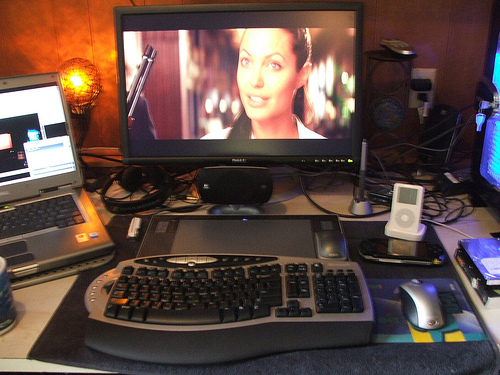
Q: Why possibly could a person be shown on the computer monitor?
A: Movie.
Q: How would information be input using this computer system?
A: Keyboard.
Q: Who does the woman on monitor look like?
A: Angelina jolie.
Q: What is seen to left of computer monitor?
A: Laptop.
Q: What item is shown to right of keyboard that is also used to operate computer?
A: Mouse.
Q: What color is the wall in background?
A: Deep orange.